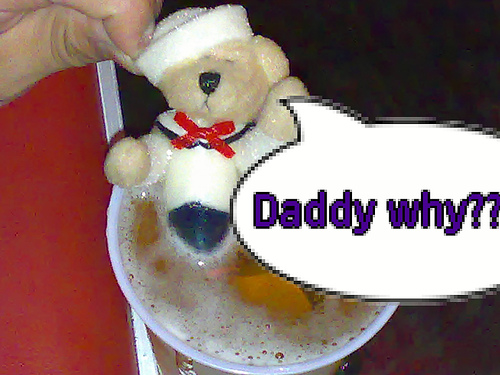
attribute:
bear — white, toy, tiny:
[108, 4, 316, 270]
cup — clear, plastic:
[122, 96, 434, 371]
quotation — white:
[250, 188, 498, 234]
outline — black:
[219, 97, 490, 319]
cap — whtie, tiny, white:
[134, 6, 256, 81]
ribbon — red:
[174, 113, 236, 159]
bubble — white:
[242, 339, 295, 362]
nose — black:
[196, 72, 222, 94]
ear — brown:
[252, 32, 295, 85]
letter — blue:
[249, 190, 281, 234]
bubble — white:
[206, 88, 499, 329]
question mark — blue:
[465, 187, 490, 237]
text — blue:
[252, 189, 499, 242]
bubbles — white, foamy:
[132, 267, 314, 371]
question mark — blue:
[480, 190, 499, 230]